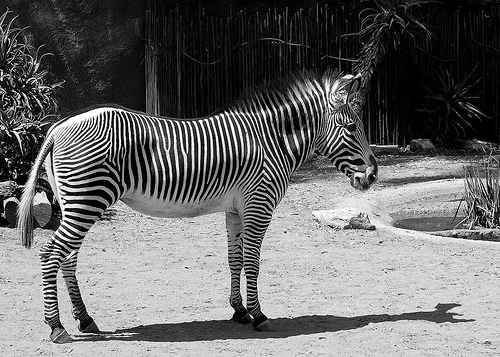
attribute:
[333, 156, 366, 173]
stripe — black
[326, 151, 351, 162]
stripe — black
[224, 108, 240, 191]
stripe — black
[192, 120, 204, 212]
stripe — black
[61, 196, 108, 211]
stripe — black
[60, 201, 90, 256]
stripe — black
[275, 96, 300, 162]
stripe — black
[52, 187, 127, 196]
stripe — black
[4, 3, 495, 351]
habitat — zebra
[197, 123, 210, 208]
stripe — black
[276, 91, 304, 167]
stripe — black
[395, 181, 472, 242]
water — drinking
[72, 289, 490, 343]
shadow — zebra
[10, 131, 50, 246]
tail — zebra's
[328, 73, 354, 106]
ear — zebra's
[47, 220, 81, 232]
stripe — black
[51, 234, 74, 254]
stripe — black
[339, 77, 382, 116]
left ear — zebra's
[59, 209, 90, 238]
stripe — black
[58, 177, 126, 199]
stripe — black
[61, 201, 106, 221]
stripe — black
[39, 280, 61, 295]
stripe — black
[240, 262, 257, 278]
stripe — black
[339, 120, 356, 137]
eye — zebra's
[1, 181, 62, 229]
wood — pile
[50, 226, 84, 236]
stripe — black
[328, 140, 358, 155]
stripe — black